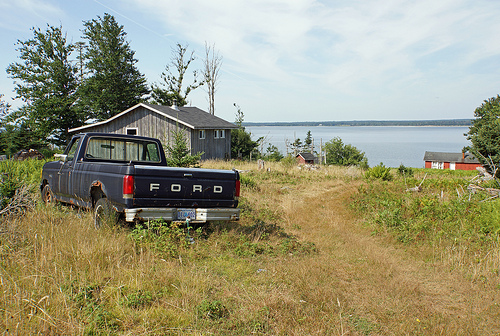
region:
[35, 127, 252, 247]
old black Ford truck sitting in field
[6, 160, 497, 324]
field filled with green grass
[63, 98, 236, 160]
gray house with white framed windows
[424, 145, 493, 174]
red house with grey roof and white framed windows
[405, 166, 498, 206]
dead branches and tree stump in grass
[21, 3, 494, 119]
clear blue sky with white clouds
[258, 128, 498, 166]
clear blue lake water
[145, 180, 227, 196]
white ford lettering on back of truck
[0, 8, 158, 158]
tall green evergreen trees in background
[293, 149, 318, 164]
small red dog house with grey roof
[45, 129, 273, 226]
black truck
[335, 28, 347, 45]
white clouds in blue sky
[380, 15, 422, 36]
white clouds in blue sky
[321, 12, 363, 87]
white clouds in blue sky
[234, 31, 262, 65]
white clouds in blue sky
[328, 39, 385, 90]
white clouds in blue sky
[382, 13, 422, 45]
white clouds in blue sky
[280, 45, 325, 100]
white clouds in blue sky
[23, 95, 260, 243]
a van in the ground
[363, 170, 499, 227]
green grass on the ground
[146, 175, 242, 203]
back part of van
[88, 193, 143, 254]
wheel of the van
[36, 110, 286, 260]
this is an old pickup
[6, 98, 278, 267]
a blue pickup truck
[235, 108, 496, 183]
this is a lake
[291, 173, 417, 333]
there is an indentation of a road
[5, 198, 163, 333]
tall yellow grass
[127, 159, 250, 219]
the back of the truckbed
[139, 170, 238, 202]
this says FORD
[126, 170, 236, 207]
the letters are white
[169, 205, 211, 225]
this is a license plate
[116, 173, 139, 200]
a red tail light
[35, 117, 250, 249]
A truck in the foreground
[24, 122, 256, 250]
A back view of a truck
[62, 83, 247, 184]
A house in the background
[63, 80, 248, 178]
The house is gray in color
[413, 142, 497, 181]
A red house in the far background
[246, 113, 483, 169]
A body of water is in the background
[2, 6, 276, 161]
Tall trees in the background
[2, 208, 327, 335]
Tall grass is dried out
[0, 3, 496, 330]
Photo was taken in the daytime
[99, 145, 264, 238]
back of the truck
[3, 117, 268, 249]
truck in the grass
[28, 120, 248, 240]
black truck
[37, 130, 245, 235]
black truck in field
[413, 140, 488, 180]
red building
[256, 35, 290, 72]
white clouds in blue sky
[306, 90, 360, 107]
white clouds in blue sky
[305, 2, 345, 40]
white clouds in blue sky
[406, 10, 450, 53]
white clouds in blue sky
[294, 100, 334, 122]
white clouds in blue sky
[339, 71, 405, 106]
white clouds in blue sky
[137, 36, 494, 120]
The cloudy sky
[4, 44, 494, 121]
A cloudy sky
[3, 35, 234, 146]
The trees to the left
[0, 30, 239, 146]
A tree to the left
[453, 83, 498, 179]
The tree to the right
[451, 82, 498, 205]
A tree to the right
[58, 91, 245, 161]
the wooden house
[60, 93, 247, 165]
A wooden house